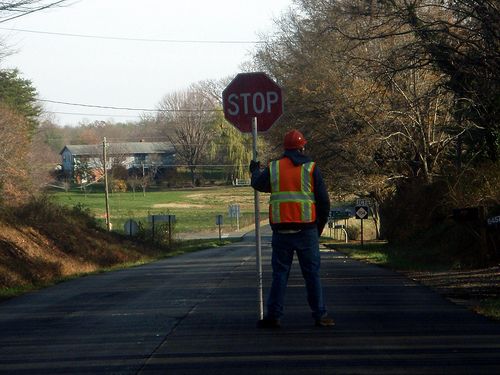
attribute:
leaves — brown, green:
[5, 80, 30, 114]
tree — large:
[237, 0, 499, 245]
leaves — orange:
[319, 60, 355, 93]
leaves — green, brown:
[256, 4, 482, 232]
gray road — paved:
[1, 227, 498, 373]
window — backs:
[66, 157, 99, 186]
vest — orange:
[268, 156, 316, 223]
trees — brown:
[249, 1, 497, 267]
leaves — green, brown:
[331, 52, 378, 87]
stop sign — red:
[215, 62, 272, 121]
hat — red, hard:
[283, 127, 307, 149]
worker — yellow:
[250, 122, 356, 336]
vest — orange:
[264, 154, 323, 221]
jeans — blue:
[265, 229, 325, 318]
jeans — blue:
[263, 227, 332, 319]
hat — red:
[260, 111, 332, 149]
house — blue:
[55, 144, 190, 172]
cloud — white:
[0, 4, 328, 126]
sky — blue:
[0, 0, 345, 123]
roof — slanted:
[95, 133, 189, 158]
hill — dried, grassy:
[0, 201, 165, 298]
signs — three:
[144, 211, 229, 243]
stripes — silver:
[268, 156, 315, 222]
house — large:
[56, 138, 176, 181]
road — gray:
[2, 200, 498, 373]